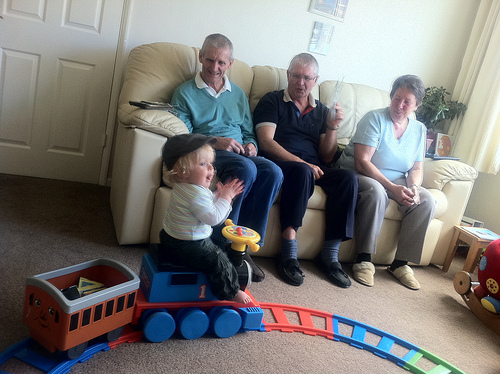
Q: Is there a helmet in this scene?
A: No, there are no helmets.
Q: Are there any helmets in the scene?
A: No, there are no helmets.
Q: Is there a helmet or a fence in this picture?
A: No, there are no helmets or fences.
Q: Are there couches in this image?
A: Yes, there is a couch.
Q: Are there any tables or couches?
A: Yes, there is a couch.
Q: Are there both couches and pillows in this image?
A: No, there is a couch but no pillows.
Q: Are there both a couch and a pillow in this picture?
A: No, there is a couch but no pillows.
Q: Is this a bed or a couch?
A: This is a couch.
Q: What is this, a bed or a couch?
A: This is a couch.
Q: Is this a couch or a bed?
A: This is a couch.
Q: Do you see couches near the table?
A: Yes, there is a couch near the table.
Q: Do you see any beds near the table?
A: No, there is a couch near the table.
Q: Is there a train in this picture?
A: Yes, there is a train.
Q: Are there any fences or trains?
A: Yes, there is a train.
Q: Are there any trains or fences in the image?
A: Yes, there is a train.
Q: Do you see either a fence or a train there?
A: Yes, there is a train.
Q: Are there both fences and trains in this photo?
A: No, there is a train but no fences.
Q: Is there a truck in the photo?
A: No, there are no trucks.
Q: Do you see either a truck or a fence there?
A: No, there are no trucks or fences.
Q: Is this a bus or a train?
A: This is a train.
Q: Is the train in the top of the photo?
A: No, the train is in the bottom of the image.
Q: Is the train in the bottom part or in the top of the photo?
A: The train is in the bottom of the image.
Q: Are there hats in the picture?
A: Yes, there is a hat.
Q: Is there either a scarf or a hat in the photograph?
A: Yes, there is a hat.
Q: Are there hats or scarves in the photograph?
A: Yes, there is a hat.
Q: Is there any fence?
A: No, there are no fences.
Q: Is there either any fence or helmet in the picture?
A: No, there are no fences or helmets.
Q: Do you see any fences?
A: No, there are no fences.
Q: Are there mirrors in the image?
A: No, there are no mirrors.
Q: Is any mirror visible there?
A: No, there are no mirrors.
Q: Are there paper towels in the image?
A: No, there are no paper towels.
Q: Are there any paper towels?
A: No, there are no paper towels.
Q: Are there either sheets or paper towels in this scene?
A: No, there are no paper towels or sheets.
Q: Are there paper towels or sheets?
A: No, there are no paper towels or sheets.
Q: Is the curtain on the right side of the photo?
A: Yes, the curtain is on the right of the image.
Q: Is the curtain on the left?
A: No, the curtain is on the right of the image.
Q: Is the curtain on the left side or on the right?
A: The curtain is on the right of the image.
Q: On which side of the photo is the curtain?
A: The curtain is on the right of the image.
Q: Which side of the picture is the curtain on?
A: The curtain is on the right of the image.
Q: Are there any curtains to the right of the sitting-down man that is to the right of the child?
A: Yes, there is a curtain to the right of the man.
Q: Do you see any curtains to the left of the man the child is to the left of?
A: No, the curtain is to the right of the man.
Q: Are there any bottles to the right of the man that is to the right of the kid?
A: No, there is a curtain to the right of the man.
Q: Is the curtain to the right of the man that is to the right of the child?
A: Yes, the curtain is to the right of the man.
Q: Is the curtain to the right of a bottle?
A: No, the curtain is to the right of the man.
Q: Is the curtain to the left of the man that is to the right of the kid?
A: No, the curtain is to the right of the man.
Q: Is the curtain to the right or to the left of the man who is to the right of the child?
A: The curtain is to the right of the man.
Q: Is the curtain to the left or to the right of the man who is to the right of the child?
A: The curtain is to the right of the man.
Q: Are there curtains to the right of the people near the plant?
A: Yes, there is a curtain to the right of the people.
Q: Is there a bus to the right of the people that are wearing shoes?
A: No, there is a curtain to the right of the people.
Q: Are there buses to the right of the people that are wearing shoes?
A: No, there is a curtain to the right of the people.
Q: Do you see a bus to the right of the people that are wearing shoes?
A: No, there is a curtain to the right of the people.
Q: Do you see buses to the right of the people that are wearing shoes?
A: No, there is a curtain to the right of the people.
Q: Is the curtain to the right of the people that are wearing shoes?
A: Yes, the curtain is to the right of the people.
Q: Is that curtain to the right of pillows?
A: No, the curtain is to the right of the people.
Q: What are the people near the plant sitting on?
A: The people are sitting on the couch.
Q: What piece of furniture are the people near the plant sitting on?
A: The people are sitting on the couch.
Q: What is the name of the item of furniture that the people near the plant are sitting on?
A: The piece of furniture is a couch.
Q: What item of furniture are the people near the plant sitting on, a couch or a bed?
A: The people are sitting on a couch.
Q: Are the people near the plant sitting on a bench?
A: No, the people are sitting on the couch.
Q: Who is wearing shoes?
A: The people are wearing shoes.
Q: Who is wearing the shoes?
A: The people are wearing shoes.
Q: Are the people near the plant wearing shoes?
A: Yes, the people are wearing shoes.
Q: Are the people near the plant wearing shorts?
A: No, the people are wearing shoes.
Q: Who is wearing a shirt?
A: The people are wearing a shirt.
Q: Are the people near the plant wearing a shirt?
A: Yes, the people are wearing a shirt.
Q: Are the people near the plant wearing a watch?
A: No, the people are wearing a shirt.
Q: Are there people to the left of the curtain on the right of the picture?
A: Yes, there are people to the left of the curtain.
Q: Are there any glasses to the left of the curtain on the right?
A: No, there are people to the left of the curtain.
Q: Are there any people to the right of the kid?
A: Yes, there are people to the right of the kid.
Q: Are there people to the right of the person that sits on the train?
A: Yes, there are people to the right of the kid.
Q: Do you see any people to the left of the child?
A: No, the people are to the right of the child.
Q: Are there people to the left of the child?
A: No, the people are to the right of the child.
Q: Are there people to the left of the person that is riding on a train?
A: No, the people are to the right of the child.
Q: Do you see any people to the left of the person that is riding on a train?
A: No, the people are to the right of the child.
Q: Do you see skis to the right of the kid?
A: No, there are people to the right of the kid.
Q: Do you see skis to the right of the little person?
A: No, there are people to the right of the kid.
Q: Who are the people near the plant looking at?
A: The people are looking at the kid.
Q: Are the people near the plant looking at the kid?
A: Yes, the people are looking at the kid.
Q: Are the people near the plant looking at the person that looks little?
A: Yes, the people are looking at the kid.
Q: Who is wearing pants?
A: The people are wearing pants.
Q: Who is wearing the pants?
A: The people are wearing pants.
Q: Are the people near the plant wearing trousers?
A: Yes, the people are wearing trousers.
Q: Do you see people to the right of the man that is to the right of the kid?
A: Yes, there are people to the right of the man.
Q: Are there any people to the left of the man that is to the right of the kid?
A: No, the people are to the right of the man.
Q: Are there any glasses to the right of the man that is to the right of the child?
A: No, there are people to the right of the man.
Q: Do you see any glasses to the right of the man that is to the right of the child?
A: No, there are people to the right of the man.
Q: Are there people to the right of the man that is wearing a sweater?
A: Yes, there are people to the right of the man.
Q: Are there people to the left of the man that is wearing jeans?
A: No, the people are to the right of the man.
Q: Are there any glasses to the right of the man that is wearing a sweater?
A: No, there are people to the right of the man.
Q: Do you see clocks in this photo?
A: No, there are no clocks.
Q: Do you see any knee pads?
A: No, there are no knee pads.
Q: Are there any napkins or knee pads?
A: No, there are no knee pads or napkins.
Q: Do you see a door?
A: Yes, there is a door.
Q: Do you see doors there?
A: Yes, there is a door.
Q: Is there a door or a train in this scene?
A: Yes, there is a door.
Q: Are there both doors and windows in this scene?
A: No, there is a door but no windows.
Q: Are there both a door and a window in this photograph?
A: No, there is a door but no windows.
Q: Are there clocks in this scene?
A: No, there are no clocks.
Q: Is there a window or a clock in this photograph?
A: No, there are no clocks or windows.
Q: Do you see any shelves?
A: No, there are no shelves.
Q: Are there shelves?
A: No, there are no shelves.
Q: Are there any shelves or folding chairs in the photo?
A: No, there are no shelves or folding chairs.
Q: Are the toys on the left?
A: Yes, the toys are on the left of the image.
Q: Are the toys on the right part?
A: No, the toys are on the left of the image.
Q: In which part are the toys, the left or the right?
A: The toys are on the left of the image.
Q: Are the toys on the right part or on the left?
A: The toys are on the left of the image.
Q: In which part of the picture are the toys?
A: The toys are on the left of the image.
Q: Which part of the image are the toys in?
A: The toys are on the left of the image.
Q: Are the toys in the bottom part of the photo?
A: Yes, the toys are in the bottom of the image.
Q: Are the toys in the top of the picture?
A: No, the toys are in the bottom of the image.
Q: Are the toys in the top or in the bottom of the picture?
A: The toys are in the bottom of the image.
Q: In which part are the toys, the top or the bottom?
A: The toys are in the bottom of the image.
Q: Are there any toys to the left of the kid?
A: Yes, there are toys to the left of the kid.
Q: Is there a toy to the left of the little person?
A: Yes, there are toys to the left of the kid.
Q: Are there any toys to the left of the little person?
A: Yes, there are toys to the left of the kid.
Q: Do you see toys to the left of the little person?
A: Yes, there are toys to the left of the kid.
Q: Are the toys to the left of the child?
A: Yes, the toys are to the left of the child.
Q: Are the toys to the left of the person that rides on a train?
A: Yes, the toys are to the left of the child.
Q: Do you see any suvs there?
A: No, there are no suvs.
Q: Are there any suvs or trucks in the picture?
A: No, there are no suvs or trucks.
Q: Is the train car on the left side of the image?
A: Yes, the train car is on the left of the image.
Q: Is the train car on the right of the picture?
A: No, the train car is on the left of the image.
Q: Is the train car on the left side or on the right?
A: The train car is on the left of the image.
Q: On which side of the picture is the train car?
A: The train car is on the left of the image.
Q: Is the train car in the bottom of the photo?
A: Yes, the train car is in the bottom of the image.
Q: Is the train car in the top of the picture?
A: No, the train car is in the bottom of the image.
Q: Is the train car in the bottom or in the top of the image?
A: The train car is in the bottom of the image.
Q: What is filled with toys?
A: The train car is filled with toys.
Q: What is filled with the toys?
A: The train car is filled with toys.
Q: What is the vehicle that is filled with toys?
A: The vehicle is a train car.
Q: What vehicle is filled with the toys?
A: The vehicle is a train car.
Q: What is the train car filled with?
A: The train car is filled with toys.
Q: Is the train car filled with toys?
A: Yes, the train car is filled with toys.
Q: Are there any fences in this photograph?
A: No, there are no fences.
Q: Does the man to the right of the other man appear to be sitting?
A: Yes, the man is sitting.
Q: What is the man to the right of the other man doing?
A: The man is sitting.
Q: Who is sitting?
A: The man is sitting.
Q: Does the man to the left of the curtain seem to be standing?
A: No, the man is sitting.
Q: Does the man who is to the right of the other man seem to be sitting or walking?
A: The man is sitting.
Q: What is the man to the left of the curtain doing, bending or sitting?
A: The man is sitting.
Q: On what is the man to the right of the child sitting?
A: The man is sitting on the couch.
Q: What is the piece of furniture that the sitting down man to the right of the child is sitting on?
A: The piece of furniture is a couch.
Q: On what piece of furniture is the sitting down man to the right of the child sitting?
A: The man is sitting on the couch.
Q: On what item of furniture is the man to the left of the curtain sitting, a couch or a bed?
A: The man is sitting on a couch.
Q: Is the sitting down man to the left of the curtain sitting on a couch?
A: Yes, the man is sitting on a couch.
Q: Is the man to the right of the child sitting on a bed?
A: No, the man is sitting on a couch.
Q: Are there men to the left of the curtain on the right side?
A: Yes, there is a man to the left of the curtain.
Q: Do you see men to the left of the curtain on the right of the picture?
A: Yes, there is a man to the left of the curtain.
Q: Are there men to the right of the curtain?
A: No, the man is to the left of the curtain.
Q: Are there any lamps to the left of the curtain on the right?
A: No, there is a man to the left of the curtain.